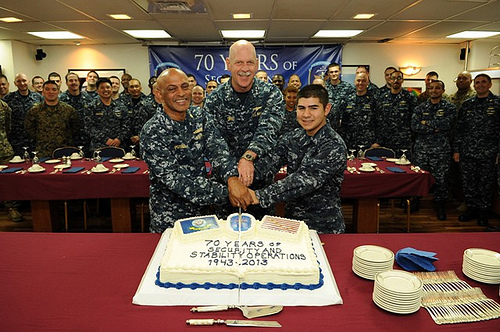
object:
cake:
[153, 211, 324, 290]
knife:
[237, 205, 242, 304]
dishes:
[373, 268, 423, 294]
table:
[0, 231, 498, 332]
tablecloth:
[1, 230, 498, 331]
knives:
[185, 318, 284, 328]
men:
[403, 79, 459, 221]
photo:
[0, 0, 500, 332]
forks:
[419, 290, 442, 326]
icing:
[160, 271, 239, 286]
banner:
[146, 42, 344, 92]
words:
[283, 60, 299, 71]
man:
[203, 39, 285, 222]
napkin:
[395, 246, 439, 271]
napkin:
[131, 227, 345, 307]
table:
[0, 157, 431, 234]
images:
[180, 216, 220, 235]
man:
[138, 67, 253, 236]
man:
[237, 83, 348, 234]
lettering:
[190, 239, 308, 266]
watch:
[241, 153, 255, 162]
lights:
[0, 0, 500, 45]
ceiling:
[0, 0, 500, 45]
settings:
[1, 145, 428, 175]